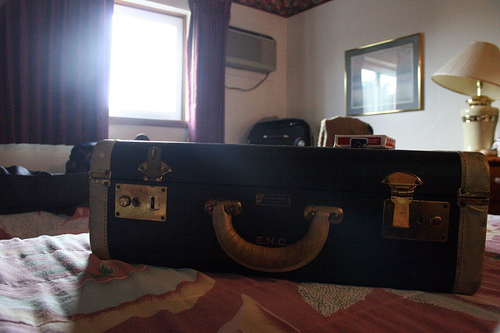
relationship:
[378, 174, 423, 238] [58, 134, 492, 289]
latch on case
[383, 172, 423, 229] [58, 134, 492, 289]
latch of case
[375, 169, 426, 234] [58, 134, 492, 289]
metal lock on case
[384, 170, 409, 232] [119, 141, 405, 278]
metal latch on case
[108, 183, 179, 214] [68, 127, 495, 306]
lock on case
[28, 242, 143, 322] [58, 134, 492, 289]
bed has case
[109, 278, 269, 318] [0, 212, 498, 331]
quilt on bed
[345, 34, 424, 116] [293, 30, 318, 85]
picture on wall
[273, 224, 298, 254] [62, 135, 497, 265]
c on case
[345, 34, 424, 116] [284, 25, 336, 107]
picture on wall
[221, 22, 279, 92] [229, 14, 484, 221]
air conditioner on wall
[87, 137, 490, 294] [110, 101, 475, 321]
case on bed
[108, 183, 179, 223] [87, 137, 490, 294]
lock on case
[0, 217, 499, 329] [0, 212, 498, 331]
bedspread covering bed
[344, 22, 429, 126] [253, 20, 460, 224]
decor to wall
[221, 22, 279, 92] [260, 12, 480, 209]
air conditioner in wall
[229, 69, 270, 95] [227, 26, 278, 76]
cord to air conditioner